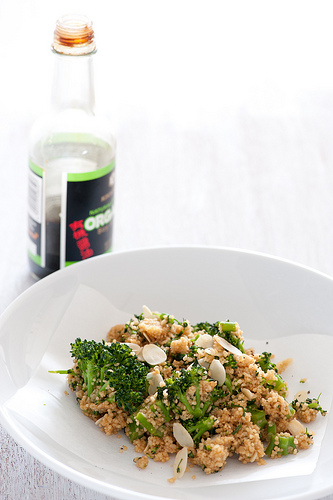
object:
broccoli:
[69, 337, 112, 399]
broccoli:
[101, 343, 147, 413]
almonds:
[173, 444, 187, 479]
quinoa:
[204, 409, 259, 468]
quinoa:
[81, 392, 115, 414]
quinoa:
[263, 394, 292, 419]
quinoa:
[148, 434, 175, 459]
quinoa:
[112, 325, 136, 342]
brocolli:
[258, 350, 273, 373]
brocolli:
[131, 410, 164, 440]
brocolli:
[265, 422, 276, 455]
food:
[60, 312, 322, 476]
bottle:
[25, 19, 116, 282]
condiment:
[41, 226, 68, 249]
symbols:
[69, 219, 96, 260]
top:
[50, 15, 96, 55]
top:
[128, 0, 330, 64]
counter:
[1, 243, 330, 496]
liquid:
[27, 207, 71, 275]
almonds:
[214, 336, 244, 356]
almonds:
[195, 334, 212, 348]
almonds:
[208, 359, 226, 387]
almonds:
[170, 422, 193, 447]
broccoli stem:
[48, 369, 72, 374]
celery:
[276, 433, 298, 455]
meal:
[63, 302, 322, 481]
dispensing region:
[51, 12, 96, 33]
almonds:
[143, 342, 169, 367]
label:
[26, 132, 115, 278]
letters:
[82, 216, 97, 232]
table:
[0, 240, 333, 500]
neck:
[48, 16, 102, 134]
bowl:
[1, 245, 332, 495]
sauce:
[51, 27, 97, 48]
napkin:
[1, 281, 332, 491]